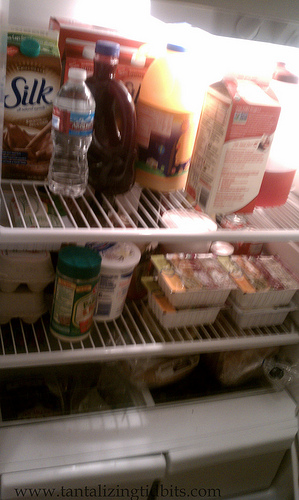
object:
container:
[101, 248, 146, 329]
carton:
[2, 27, 62, 182]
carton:
[165, 449, 298, 498]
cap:
[20, 38, 40, 57]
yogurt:
[90, 242, 141, 323]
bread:
[115, 337, 280, 385]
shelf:
[1, 180, 298, 415]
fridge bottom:
[1, 393, 296, 497]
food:
[0, 0, 299, 388]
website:
[15, 480, 221, 499]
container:
[49, 245, 102, 342]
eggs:
[0, 251, 55, 326]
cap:
[167, 43, 186, 53]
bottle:
[136, 43, 195, 193]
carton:
[184, 74, 281, 217]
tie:
[259, 354, 267, 369]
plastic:
[211, 354, 296, 399]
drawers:
[0, 424, 299, 499]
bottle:
[47, 66, 95, 198]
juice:
[133, 38, 199, 192]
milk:
[183, 74, 281, 213]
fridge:
[0, 0, 299, 499]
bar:
[5, 165, 293, 362]